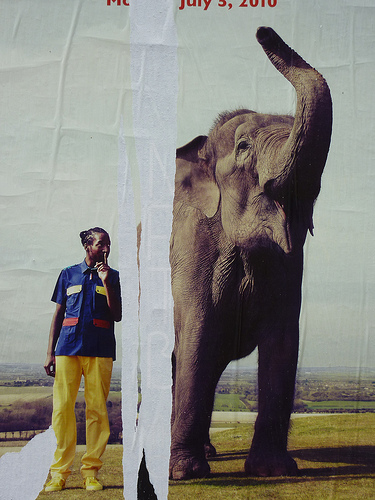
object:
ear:
[174, 133, 219, 218]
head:
[177, 107, 328, 255]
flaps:
[63, 316, 80, 327]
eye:
[235, 136, 254, 157]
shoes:
[84, 476, 104, 492]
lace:
[47, 471, 65, 489]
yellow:
[47, 355, 113, 497]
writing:
[176, 38, 278, 39]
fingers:
[104, 252, 108, 265]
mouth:
[98, 252, 109, 258]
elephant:
[136, 25, 333, 482]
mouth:
[268, 191, 315, 255]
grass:
[37, 411, 375, 496]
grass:
[304, 399, 362, 406]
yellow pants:
[47, 351, 112, 482]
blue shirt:
[50, 257, 122, 362]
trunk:
[255, 25, 334, 205]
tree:
[0, 405, 11, 440]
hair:
[79, 223, 112, 253]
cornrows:
[79, 225, 108, 253]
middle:
[117, 220, 171, 498]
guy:
[42, 227, 122, 494]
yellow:
[67, 285, 83, 296]